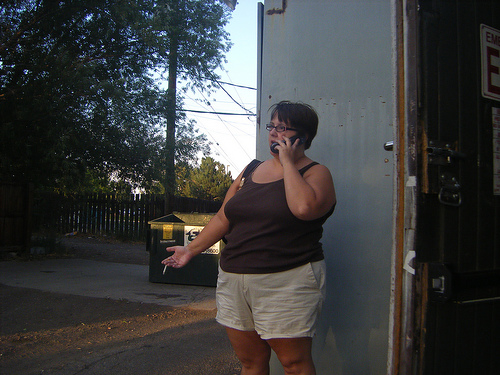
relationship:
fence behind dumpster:
[57, 183, 197, 241] [138, 214, 222, 294]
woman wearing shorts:
[162, 100, 337, 374] [213, 249, 328, 341]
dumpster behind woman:
[141, 210, 223, 286] [162, 100, 337, 374]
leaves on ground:
[68, 295, 159, 361] [42, 255, 147, 350]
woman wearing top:
[162, 100, 337, 374] [215, 154, 326, 274]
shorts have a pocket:
[215, 249, 323, 338] [298, 262, 320, 288]